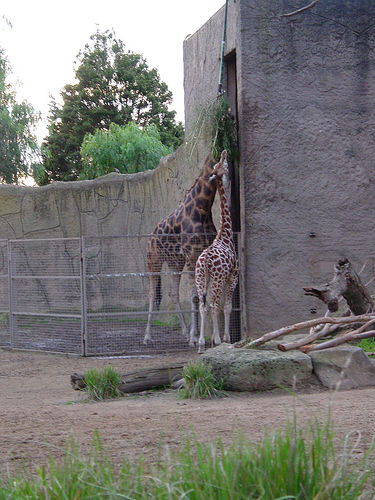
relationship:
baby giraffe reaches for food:
[194, 147, 239, 353] [187, 97, 242, 162]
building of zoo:
[0, 2, 373, 353] [0, 3, 372, 497]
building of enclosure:
[0, 2, 373, 353] [3, 1, 371, 496]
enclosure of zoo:
[3, 1, 371, 496] [0, 3, 372, 497]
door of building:
[208, 41, 248, 349] [177, 6, 374, 336]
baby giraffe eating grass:
[194, 147, 239, 353] [80, 366, 123, 403]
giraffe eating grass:
[138, 98, 236, 342] [180, 360, 226, 399]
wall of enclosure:
[3, 159, 231, 335] [8, 4, 370, 353]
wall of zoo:
[3, 159, 231, 335] [0, 3, 372, 497]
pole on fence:
[68, 227, 95, 343] [0, 228, 244, 357]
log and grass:
[68, 357, 192, 393] [88, 337, 134, 409]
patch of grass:
[1, 427, 368, 497] [7, 431, 373, 486]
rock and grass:
[187, 344, 315, 392] [7, 431, 373, 486]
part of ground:
[149, 404, 189, 451] [109, 358, 132, 374]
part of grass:
[246, 444, 286, 493] [224, 437, 326, 468]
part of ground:
[149, 404, 189, 451] [14, 374, 147, 461]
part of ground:
[149, 404, 189, 451] [6, 346, 374, 498]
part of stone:
[220, 352, 244, 384] [164, 331, 333, 393]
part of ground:
[149, 404, 189, 451] [0, 354, 371, 493]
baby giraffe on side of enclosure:
[194, 147, 239, 353] [8, 4, 370, 353]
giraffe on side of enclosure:
[138, 98, 236, 342] [8, 4, 370, 353]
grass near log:
[183, 363, 229, 393] [72, 365, 187, 394]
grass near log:
[82, 366, 121, 397] [72, 365, 187, 394]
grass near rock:
[178, 363, 225, 399] [187, 344, 315, 392]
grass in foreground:
[40, 427, 326, 498] [2, 411, 370, 498]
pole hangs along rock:
[217, 14, 228, 92] [308, 343, 373, 391]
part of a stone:
[246, 352, 278, 388] [200, 339, 316, 389]